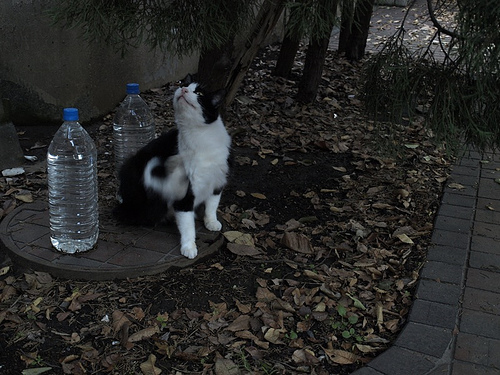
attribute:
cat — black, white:
[132, 76, 275, 206]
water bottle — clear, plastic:
[44, 104, 101, 256]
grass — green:
[337, 302, 377, 336]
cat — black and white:
[152, 85, 223, 227]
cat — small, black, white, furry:
[112, 69, 241, 258]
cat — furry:
[135, 75, 227, 251]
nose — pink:
[170, 99, 194, 102]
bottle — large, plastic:
[46, 96, 101, 254]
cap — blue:
[60, 109, 81, 133]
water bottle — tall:
[40, 104, 99, 272]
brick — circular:
[28, 69, 286, 279]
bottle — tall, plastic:
[37, 76, 149, 245]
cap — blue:
[49, 105, 83, 128]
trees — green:
[91, 63, 404, 93]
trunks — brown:
[335, 100, 358, 123]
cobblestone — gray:
[422, 129, 495, 371]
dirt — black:
[242, 158, 384, 334]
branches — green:
[344, 50, 464, 123]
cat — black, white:
[118, 61, 250, 253]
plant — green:
[329, 304, 360, 341]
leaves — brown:
[231, 95, 425, 363]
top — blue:
[127, 81, 140, 99]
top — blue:
[58, 103, 74, 123]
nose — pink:
[177, 88, 187, 90]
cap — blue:
[62, 105, 77, 124]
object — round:
[18, 189, 223, 274]